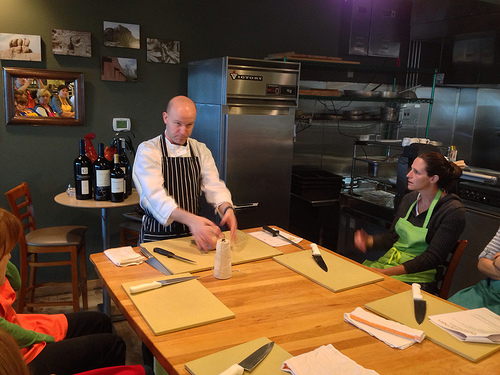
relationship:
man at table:
[131, 94, 237, 255] [78, 195, 474, 371]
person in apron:
[354, 150, 467, 292] [364, 190, 441, 291]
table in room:
[88, 225, 498, 374] [2, 6, 497, 373]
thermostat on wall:
[112, 116, 130, 131] [1, 0, 406, 287]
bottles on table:
[73, 138, 132, 203] [51, 184, 149, 307]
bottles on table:
[90, 140, 117, 197] [51, 184, 149, 307]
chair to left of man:
[3, 180, 89, 312] [131, 94, 237, 255]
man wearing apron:
[131, 94, 237, 255] [128, 135, 215, 245]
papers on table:
[343, 306, 500, 350] [88, 225, 498, 374]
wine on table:
[73, 139, 128, 201] [55, 193, 140, 206]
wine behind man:
[73, 139, 128, 201] [131, 94, 237, 255]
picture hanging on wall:
[0, 31, 42, 63] [2, 0, 342, 284]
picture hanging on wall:
[0, 22, 181, 127] [2, 0, 342, 284]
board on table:
[121, 272, 235, 336] [88, 225, 498, 374]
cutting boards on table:
[182, 335, 294, 373] [88, 225, 498, 374]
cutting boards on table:
[358, 285, 498, 371] [88, 225, 498, 374]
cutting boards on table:
[276, 249, 383, 295] [88, 225, 498, 374]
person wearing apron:
[354, 150, 467, 292] [381, 203, 442, 270]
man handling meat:
[131, 94, 237, 255] [192, 219, 224, 250]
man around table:
[131, 94, 237, 255] [88, 225, 498, 374]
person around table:
[364, 145, 465, 290] [88, 225, 498, 374]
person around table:
[448, 219, 498, 315] [88, 225, 498, 374]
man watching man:
[131, 94, 237, 255] [131, 94, 237, 255]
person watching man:
[364, 145, 465, 290] [131, 94, 237, 255]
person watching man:
[448, 219, 498, 315] [131, 94, 237, 255]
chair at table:
[3, 182, 89, 314] [53, 180, 142, 312]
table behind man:
[53, 180, 142, 312] [131, 94, 237, 255]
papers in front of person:
[362, 276, 499, 366] [448, 219, 498, 315]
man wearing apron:
[131, 94, 237, 255] [142, 130, 203, 240]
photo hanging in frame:
[2, 59, 97, 115] [0, 65, 88, 127]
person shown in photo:
[13, 74, 35, 114] [2, 59, 97, 115]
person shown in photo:
[33, 85, 56, 115] [2, 59, 97, 115]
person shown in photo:
[48, 81, 76, 117] [2, 59, 97, 115]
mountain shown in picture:
[105, 22, 140, 48] [100, 15, 143, 48]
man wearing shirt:
[131, 94, 237, 255] [129, 133, 237, 233]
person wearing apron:
[354, 150, 467, 292] [360, 184, 443, 284]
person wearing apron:
[354, 150, 467, 292] [366, 187, 456, 279]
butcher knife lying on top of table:
[412, 283, 427, 326] [88, 225, 498, 374]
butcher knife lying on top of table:
[309, 243, 328, 273] [88, 225, 498, 374]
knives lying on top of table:
[221, 338, 275, 373] [88, 225, 498, 374]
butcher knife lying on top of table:
[129, 275, 201, 293] [88, 225, 498, 374]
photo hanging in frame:
[14, 77, 77, 119] [4, 65, 105, 160]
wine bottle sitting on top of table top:
[73, 139, 133, 203] [51, 166, 143, 213]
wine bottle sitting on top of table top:
[83, 130, 97, 162] [51, 166, 143, 213]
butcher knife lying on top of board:
[129, 275, 201, 293] [121, 272, 234, 334]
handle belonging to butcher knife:
[128, 281, 162, 293] [129, 275, 201, 293]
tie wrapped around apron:
[385, 244, 417, 264] [361, 190, 452, 292]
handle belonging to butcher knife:
[307, 241, 322, 256] [308, 241, 327, 274]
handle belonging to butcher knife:
[410, 281, 423, 301] [410, 281, 426, 326]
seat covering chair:
[21, 218, 89, 245] [3, 182, 95, 307]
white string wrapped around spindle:
[213, 240, 230, 278] [210, 235, 235, 280]